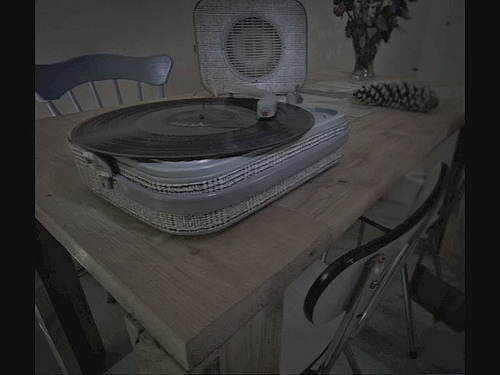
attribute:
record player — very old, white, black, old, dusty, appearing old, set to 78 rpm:
[65, 87, 351, 238]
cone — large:
[354, 83, 439, 113]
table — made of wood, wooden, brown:
[34, 68, 467, 369]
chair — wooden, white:
[34, 54, 173, 116]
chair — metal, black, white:
[280, 161, 448, 373]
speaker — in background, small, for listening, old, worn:
[194, 0, 308, 97]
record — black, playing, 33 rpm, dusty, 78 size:
[67, 96, 315, 160]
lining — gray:
[68, 106, 348, 237]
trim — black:
[305, 162, 450, 324]